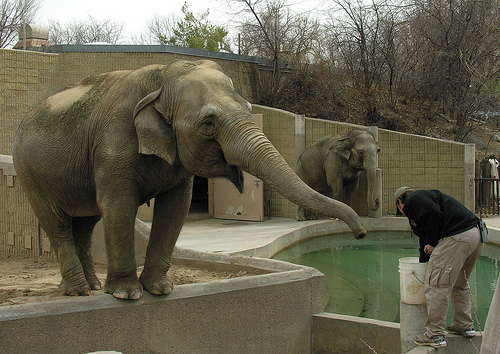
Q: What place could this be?
A: It is a zoo.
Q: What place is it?
A: It is a zoo.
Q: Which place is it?
A: It is a zoo.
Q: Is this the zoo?
A: Yes, it is the zoo.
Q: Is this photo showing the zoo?
A: Yes, it is showing the zoo.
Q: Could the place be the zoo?
A: Yes, it is the zoo.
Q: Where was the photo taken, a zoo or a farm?
A: It was taken at a zoo.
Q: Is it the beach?
A: No, it is the zoo.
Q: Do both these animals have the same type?
A: Yes, all the animals are elephants.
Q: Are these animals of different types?
A: No, all the animals are elephants.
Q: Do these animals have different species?
A: No, all the animals are elephants.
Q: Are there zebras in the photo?
A: No, there are no zebras.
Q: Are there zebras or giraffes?
A: No, there are no zebras or giraffes.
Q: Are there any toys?
A: No, there are no toys.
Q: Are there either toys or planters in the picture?
A: No, there are no toys or planters.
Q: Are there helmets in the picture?
A: No, there are no helmets.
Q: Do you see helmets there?
A: No, there are no helmets.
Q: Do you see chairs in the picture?
A: No, there are no chairs.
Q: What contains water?
A: The pool contains water.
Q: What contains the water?
A: The pool contains water.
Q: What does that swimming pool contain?
A: The swimming pool contains water.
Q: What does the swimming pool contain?
A: The swimming pool contains water.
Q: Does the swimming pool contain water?
A: Yes, the swimming pool contains water.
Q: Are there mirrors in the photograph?
A: No, there are no mirrors.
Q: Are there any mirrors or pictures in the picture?
A: No, there are no mirrors or pictures.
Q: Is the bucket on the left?
A: No, the bucket is on the right of the image.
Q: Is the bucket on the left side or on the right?
A: The bucket is on the right of the image.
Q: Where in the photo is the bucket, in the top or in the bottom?
A: The bucket is in the bottom of the image.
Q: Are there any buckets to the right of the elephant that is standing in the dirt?
A: Yes, there is a bucket to the right of the elephant.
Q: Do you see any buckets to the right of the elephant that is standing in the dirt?
A: Yes, there is a bucket to the right of the elephant.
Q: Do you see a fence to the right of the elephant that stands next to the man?
A: No, there is a bucket to the right of the elephant.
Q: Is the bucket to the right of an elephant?
A: Yes, the bucket is to the right of an elephant.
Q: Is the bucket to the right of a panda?
A: No, the bucket is to the right of an elephant.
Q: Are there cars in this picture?
A: No, there are no cars.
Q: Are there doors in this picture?
A: Yes, there is a door.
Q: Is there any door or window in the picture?
A: Yes, there is a door.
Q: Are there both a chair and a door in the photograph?
A: No, there is a door but no chairs.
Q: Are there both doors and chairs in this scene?
A: No, there is a door but no chairs.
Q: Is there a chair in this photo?
A: No, there are no chairs.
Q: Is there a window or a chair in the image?
A: No, there are no chairs or windows.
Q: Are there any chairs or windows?
A: No, there are no chairs or windows.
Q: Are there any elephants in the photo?
A: Yes, there is an elephant.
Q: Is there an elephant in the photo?
A: Yes, there is an elephant.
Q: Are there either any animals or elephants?
A: Yes, there is an elephant.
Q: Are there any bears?
A: No, there are no bears.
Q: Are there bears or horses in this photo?
A: No, there are no bears or horses.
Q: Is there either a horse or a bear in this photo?
A: No, there are no bears or horses.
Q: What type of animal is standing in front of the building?
A: The animal is an elephant.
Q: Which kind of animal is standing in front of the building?
A: The animal is an elephant.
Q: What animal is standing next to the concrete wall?
A: The elephant is standing next to the wall.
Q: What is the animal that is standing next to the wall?
A: The animal is an elephant.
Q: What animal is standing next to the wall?
A: The animal is an elephant.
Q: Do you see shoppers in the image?
A: No, there are no shoppers.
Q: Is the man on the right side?
A: Yes, the man is on the right of the image.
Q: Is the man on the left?
A: No, the man is on the right of the image.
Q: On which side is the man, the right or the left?
A: The man is on the right of the image.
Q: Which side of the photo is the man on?
A: The man is on the right of the image.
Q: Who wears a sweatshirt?
A: The man wears a sweatshirt.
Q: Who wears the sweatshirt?
A: The man wears a sweatshirt.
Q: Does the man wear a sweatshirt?
A: Yes, the man wears a sweatshirt.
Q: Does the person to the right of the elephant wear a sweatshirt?
A: Yes, the man wears a sweatshirt.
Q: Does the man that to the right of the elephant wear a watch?
A: No, the man wears a sweatshirt.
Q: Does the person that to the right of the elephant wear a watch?
A: No, the man wears a sweatshirt.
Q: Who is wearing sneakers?
A: The man is wearing sneakers.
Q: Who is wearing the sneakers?
A: The man is wearing sneakers.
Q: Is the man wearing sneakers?
A: Yes, the man is wearing sneakers.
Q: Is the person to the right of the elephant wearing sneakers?
A: Yes, the man is wearing sneakers.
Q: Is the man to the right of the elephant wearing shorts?
A: No, the man is wearing sneakers.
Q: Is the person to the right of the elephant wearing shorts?
A: No, the man is wearing sneakers.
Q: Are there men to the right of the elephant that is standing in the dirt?
A: Yes, there is a man to the right of the elephant.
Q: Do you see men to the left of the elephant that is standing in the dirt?
A: No, the man is to the right of the elephant.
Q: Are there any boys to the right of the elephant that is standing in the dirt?
A: No, there is a man to the right of the elephant.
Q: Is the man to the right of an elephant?
A: Yes, the man is to the right of an elephant.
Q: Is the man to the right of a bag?
A: No, the man is to the right of an elephant.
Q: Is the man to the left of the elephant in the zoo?
A: No, the man is to the right of the elephant.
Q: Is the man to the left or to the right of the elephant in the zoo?
A: The man is to the right of the elephant.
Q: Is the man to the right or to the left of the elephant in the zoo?
A: The man is to the right of the elephant.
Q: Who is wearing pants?
A: The man is wearing pants.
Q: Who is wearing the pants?
A: The man is wearing pants.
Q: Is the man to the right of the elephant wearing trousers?
A: Yes, the man is wearing trousers.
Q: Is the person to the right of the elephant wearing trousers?
A: Yes, the man is wearing trousers.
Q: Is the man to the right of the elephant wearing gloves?
A: No, the man is wearing trousers.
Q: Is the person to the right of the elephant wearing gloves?
A: No, the man is wearing trousers.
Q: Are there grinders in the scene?
A: No, there are no grinders.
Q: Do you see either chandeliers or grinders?
A: No, there are no grinders or chandeliers.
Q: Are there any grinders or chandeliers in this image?
A: No, there are no grinders or chandeliers.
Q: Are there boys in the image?
A: No, there are no boys.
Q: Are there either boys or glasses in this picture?
A: No, there are no boys or glasses.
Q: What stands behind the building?
A: The tree stands behind the building.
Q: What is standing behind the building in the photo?
A: The tree is standing behind the building.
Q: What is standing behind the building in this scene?
A: The tree is standing behind the building.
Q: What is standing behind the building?
A: The tree is standing behind the building.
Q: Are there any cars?
A: No, there are no cars.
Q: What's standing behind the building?
A: The tree is standing behind the building.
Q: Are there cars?
A: No, there are no cars.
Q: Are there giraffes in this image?
A: No, there are no giraffes.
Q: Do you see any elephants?
A: Yes, there is an elephant.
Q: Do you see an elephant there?
A: Yes, there is an elephant.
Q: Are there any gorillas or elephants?
A: Yes, there is an elephant.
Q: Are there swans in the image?
A: No, there are no swans.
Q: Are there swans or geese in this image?
A: No, there are no swans or geese.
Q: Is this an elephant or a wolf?
A: This is an elephant.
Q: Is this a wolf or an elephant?
A: This is an elephant.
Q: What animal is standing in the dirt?
A: The animal is an elephant.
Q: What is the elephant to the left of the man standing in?
A: The elephant is standing in the dirt.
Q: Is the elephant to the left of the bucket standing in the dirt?
A: Yes, the elephant is standing in the dirt.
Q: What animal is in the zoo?
A: The elephant is in the zoo.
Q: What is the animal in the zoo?
A: The animal is an elephant.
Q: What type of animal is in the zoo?
A: The animal is an elephant.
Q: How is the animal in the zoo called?
A: The animal is an elephant.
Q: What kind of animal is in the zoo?
A: The animal is an elephant.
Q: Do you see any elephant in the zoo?
A: Yes, there is an elephant in the zoo.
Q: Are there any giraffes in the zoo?
A: No, there is an elephant in the zoo.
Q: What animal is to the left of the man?
A: The animal is an elephant.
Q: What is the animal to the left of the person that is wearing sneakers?
A: The animal is an elephant.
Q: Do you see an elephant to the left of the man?
A: Yes, there is an elephant to the left of the man.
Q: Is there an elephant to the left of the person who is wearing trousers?
A: Yes, there is an elephant to the left of the man.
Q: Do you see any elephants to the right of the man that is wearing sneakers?
A: No, the elephant is to the left of the man.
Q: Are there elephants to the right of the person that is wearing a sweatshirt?
A: No, the elephant is to the left of the man.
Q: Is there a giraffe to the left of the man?
A: No, there is an elephant to the left of the man.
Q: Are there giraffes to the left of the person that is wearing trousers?
A: No, there is an elephant to the left of the man.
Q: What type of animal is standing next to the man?
A: The animal is an elephant.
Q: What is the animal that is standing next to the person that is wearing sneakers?
A: The animal is an elephant.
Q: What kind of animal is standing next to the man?
A: The animal is an elephant.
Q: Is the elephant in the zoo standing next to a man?
A: Yes, the elephant is standing next to a man.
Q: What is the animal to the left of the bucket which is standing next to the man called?
A: The animal is an elephant.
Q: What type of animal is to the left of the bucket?
A: The animal is an elephant.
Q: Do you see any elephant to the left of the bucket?
A: Yes, there is an elephant to the left of the bucket.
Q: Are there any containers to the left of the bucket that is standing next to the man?
A: No, there is an elephant to the left of the bucket.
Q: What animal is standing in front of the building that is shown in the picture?
A: The elephant is standing in front of the building.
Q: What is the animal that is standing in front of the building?
A: The animal is an elephant.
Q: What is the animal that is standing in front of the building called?
A: The animal is an elephant.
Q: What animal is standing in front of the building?
A: The animal is an elephant.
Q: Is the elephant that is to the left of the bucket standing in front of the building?
A: Yes, the elephant is standing in front of the building.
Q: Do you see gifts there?
A: No, there are no gifts.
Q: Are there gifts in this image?
A: No, there are no gifts.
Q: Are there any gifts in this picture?
A: No, there are no gifts.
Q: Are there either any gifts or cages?
A: No, there are no gifts or cages.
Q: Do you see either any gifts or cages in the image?
A: No, there are no gifts or cages.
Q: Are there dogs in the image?
A: No, there are no dogs.